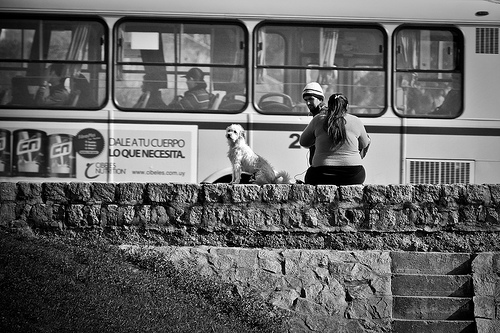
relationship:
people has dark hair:
[296, 94, 373, 187] [317, 86, 357, 151]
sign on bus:
[2, 123, 202, 183] [2, 2, 492, 191]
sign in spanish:
[2, 123, 202, 183] [105, 135, 190, 165]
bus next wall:
[2, 2, 492, 191] [2, 177, 499, 255]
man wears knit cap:
[298, 74, 329, 119] [295, 79, 331, 98]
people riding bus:
[4, 53, 448, 116] [2, 2, 492, 191]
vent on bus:
[402, 154, 480, 186] [2, 2, 492, 191]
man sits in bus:
[27, 61, 77, 111] [2, 2, 492, 191]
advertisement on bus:
[2, 123, 202, 183] [2, 2, 492, 191]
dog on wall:
[220, 114, 292, 189] [2, 177, 499, 255]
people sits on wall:
[296, 94, 373, 187] [2, 177, 499, 255]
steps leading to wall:
[385, 246, 480, 332] [2, 177, 499, 255]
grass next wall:
[2, 223, 295, 332] [2, 177, 499, 255]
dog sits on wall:
[220, 114, 292, 189] [2, 177, 499, 255]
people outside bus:
[290, 77, 373, 187] [2, 2, 492, 191]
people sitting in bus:
[4, 53, 448, 116] [2, 2, 492, 191]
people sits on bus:
[4, 53, 448, 116] [2, 2, 492, 191]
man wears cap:
[168, 62, 217, 115] [175, 66, 210, 80]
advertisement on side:
[2, 123, 202, 183] [6, 103, 497, 188]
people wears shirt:
[296, 94, 373, 187] [306, 110, 367, 171]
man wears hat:
[168, 62, 217, 115] [175, 66, 210, 80]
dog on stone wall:
[220, 114, 292, 189] [2, 177, 499, 255]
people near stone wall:
[290, 77, 373, 187] [2, 177, 499, 255]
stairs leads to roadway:
[385, 246, 480, 332] [107, 237, 500, 260]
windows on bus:
[3, 10, 470, 125] [2, 2, 492, 191]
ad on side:
[2, 123, 202, 183] [6, 103, 497, 188]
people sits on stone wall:
[296, 94, 373, 187] [2, 177, 499, 255]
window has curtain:
[3, 10, 470, 125] [64, 23, 96, 75]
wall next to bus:
[2, 177, 499, 255] [2, 2, 492, 191]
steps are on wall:
[385, 246, 480, 332] [0, 187, 492, 330]